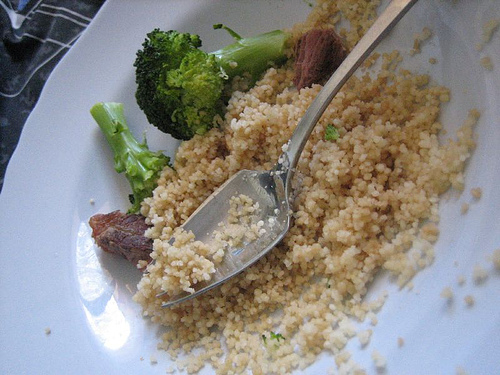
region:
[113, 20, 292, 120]
broccoli on a plate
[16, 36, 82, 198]
slight scalloped edge on white plate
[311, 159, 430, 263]
cooked quinoa in the plate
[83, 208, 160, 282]
piece of meat on the plate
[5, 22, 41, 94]
table cloth on the table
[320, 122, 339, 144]
tiny piece of broccoli in the quinoa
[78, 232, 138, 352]
reflection of light in the plate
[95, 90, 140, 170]
broccoli stem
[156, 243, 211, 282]
quinoa in the spoon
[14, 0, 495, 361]
white plate filled with food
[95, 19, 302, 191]
two pieces of green broccoli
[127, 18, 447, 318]
silver spork on plate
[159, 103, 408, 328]
yellow quinoa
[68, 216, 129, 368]
light reflecting on plate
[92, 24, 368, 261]
two small pieces of red meat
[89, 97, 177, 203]
green stem of broccoli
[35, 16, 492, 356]
plate of half eaten food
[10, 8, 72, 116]
blaack blanket with white stripes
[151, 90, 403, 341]
brown rice on plate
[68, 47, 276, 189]
green broccoli on plate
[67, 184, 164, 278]
brown meat on plate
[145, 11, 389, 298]
metal spoon on plate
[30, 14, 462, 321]
plate is white and round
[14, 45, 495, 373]
plate on grey cloth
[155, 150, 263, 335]
brown rice on spoon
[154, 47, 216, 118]
light green broccoli florets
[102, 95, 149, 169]
green stems of broccoli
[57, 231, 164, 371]
light shines on plate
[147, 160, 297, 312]
the spork end in the dinner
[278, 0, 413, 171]
the silver handle of the spork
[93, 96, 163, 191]
the green stem of the brocolli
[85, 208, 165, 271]
a brown piece of stak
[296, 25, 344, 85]
a piece of steak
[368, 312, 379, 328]
a tiny piece of cous cous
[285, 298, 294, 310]
a tiny piece of cous cous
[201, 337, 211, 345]
a tiny piece of cous cous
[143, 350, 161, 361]
a tiny piece of cous cous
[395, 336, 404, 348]
a tiny piece of cous cous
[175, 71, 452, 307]
a plate half full of food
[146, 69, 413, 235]
food is apetising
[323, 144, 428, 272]
the food is brown in color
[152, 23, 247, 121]
the vegetable are green in color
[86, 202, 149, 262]
a piece of meat is maroon in color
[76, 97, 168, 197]
stalk of bacoon is green in color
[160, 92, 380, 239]
spoonis holiding some food from plate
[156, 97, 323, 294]
spoon is silvery in color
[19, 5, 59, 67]
table mat is black with white stripes in color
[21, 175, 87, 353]
plate is white in color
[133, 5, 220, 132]
brocolli on the plate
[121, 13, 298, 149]
green broccoli on white plate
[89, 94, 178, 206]
green broccoli on white plate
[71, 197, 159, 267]
red ham on white plate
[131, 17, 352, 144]
piece of ham by broccoli